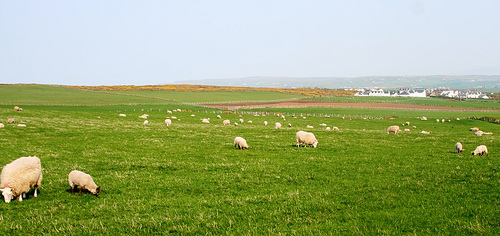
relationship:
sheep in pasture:
[1, 152, 47, 205] [2, 85, 497, 235]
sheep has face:
[1, 152, 47, 205] [1, 184, 13, 203]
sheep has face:
[66, 169, 106, 197] [94, 184, 104, 195]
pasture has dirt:
[2, 85, 497, 235] [203, 99, 493, 113]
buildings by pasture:
[352, 84, 427, 100] [2, 85, 497, 235]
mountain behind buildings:
[185, 74, 498, 91] [352, 84, 427, 100]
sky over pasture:
[1, 1, 499, 76] [2, 85, 497, 235]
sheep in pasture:
[233, 133, 250, 152] [2, 85, 497, 235]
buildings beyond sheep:
[352, 84, 427, 100] [384, 123, 403, 136]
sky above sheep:
[1, 1, 499, 76] [233, 133, 250, 152]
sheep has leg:
[1, 152, 47, 205] [33, 184, 40, 199]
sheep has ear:
[1, 152, 47, 205] [8, 186, 17, 192]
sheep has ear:
[1, 152, 47, 205] [0, 185, 5, 194]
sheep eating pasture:
[66, 169, 106, 197] [2, 85, 497, 235]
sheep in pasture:
[66, 169, 106, 197] [2, 85, 497, 235]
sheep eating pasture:
[1, 152, 47, 205] [2, 85, 497, 235]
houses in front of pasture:
[435, 88, 492, 102] [2, 85, 497, 235]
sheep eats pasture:
[1, 152, 47, 205] [2, 85, 497, 235]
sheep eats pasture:
[66, 169, 106, 197] [2, 85, 497, 235]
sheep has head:
[1, 152, 47, 205] [1, 184, 13, 203]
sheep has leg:
[66, 169, 106, 197] [69, 185, 77, 198]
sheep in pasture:
[294, 126, 321, 150] [2, 85, 497, 235]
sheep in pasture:
[470, 143, 491, 159] [2, 85, 497, 235]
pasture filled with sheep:
[2, 85, 497, 235] [1, 152, 47, 205]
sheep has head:
[66, 169, 106, 197] [94, 184, 104, 195]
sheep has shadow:
[294, 126, 321, 150] [291, 142, 307, 150]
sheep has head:
[66, 169, 106, 197] [93, 181, 102, 197]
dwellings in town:
[355, 84, 486, 106] [339, 66, 498, 105]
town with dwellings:
[339, 66, 498, 105] [355, 84, 486, 106]